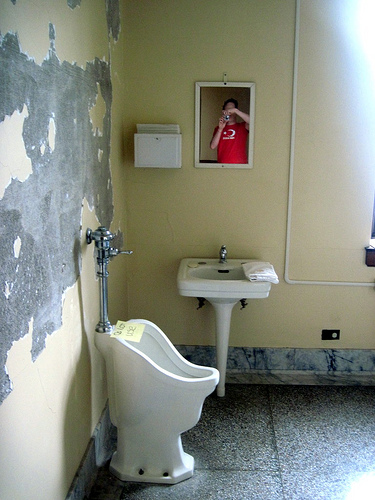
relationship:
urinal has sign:
[95, 317, 219, 485] [110, 321, 146, 343]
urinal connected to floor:
[95, 317, 219, 485] [86, 382, 374, 500]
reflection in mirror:
[211, 98, 249, 162] [200, 88, 249, 163]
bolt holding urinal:
[162, 471, 170, 477] [95, 317, 219, 485]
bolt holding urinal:
[139, 469, 145, 474] [95, 317, 219, 485]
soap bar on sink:
[187, 260, 199, 268] [176, 256, 272, 300]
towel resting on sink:
[241, 261, 279, 283] [176, 256, 272, 300]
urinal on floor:
[95, 317, 219, 485] [86, 382, 374, 500]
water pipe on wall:
[282, 0, 374, 287] [125, 0, 374, 349]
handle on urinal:
[120, 249, 133, 255] [95, 317, 219, 485]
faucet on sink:
[219, 244, 229, 260] [176, 256, 272, 300]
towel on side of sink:
[241, 261, 279, 283] [176, 256, 272, 300]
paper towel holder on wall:
[132, 122, 184, 169] [125, 0, 374, 349]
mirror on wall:
[200, 88, 249, 163] [125, 0, 374, 349]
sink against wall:
[176, 256, 272, 300] [125, 0, 374, 349]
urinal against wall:
[95, 317, 219, 485] [0, 0, 126, 499]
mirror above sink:
[200, 88, 249, 163] [176, 256, 272, 300]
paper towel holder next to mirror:
[132, 122, 184, 169] [200, 88, 249, 163]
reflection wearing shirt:
[211, 98, 249, 162] [213, 123, 249, 163]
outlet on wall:
[321, 330, 340, 340] [125, 0, 374, 349]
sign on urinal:
[110, 321, 146, 343] [95, 317, 219, 485]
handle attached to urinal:
[120, 249, 133, 255] [95, 317, 219, 485]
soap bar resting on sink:
[187, 260, 199, 268] [176, 256, 272, 300]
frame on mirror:
[194, 81, 254, 169] [200, 88, 249, 163]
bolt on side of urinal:
[162, 471, 170, 477] [95, 317, 219, 485]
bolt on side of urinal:
[139, 469, 145, 474] [95, 317, 219, 485]